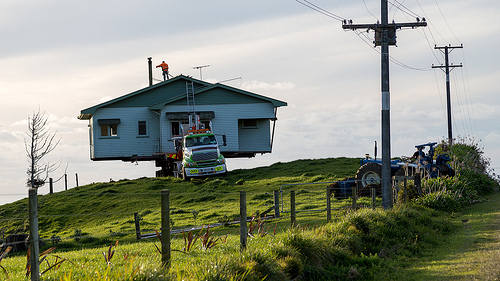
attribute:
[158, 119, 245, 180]
truck — side view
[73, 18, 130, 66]
sky — blue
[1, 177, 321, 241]
grass — green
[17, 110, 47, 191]
tree — on left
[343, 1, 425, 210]
pole — telephone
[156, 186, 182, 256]
post — black, grey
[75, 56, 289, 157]
house — large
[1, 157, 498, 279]
field grass — green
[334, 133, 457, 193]
tractor — blue, white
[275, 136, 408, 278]
hills — tall, grassy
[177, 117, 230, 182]
truck — white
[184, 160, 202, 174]
lights — green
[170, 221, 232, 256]
grass — red , gold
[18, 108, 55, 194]
tree — bare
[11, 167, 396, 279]
fence — wooden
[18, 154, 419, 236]
hills — green, rolling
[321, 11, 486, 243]
pole — white, grey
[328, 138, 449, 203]
tractor — blue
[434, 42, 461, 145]
pole — telephone